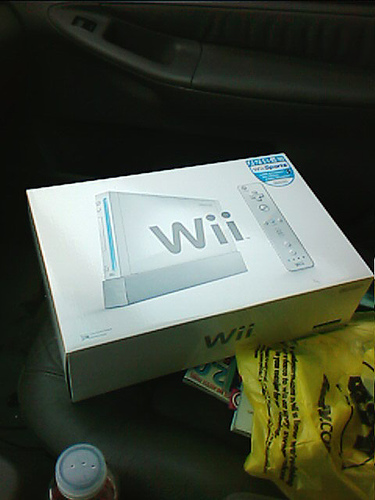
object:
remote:
[237, 178, 315, 274]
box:
[21, 150, 374, 405]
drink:
[43, 441, 122, 498]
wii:
[22, 147, 374, 404]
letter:
[146, 214, 211, 255]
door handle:
[50, 8, 208, 95]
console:
[94, 189, 249, 311]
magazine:
[181, 350, 240, 404]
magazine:
[229, 380, 255, 438]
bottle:
[47, 443, 117, 499]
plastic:
[108, 483, 116, 495]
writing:
[149, 209, 247, 255]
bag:
[229, 306, 374, 499]